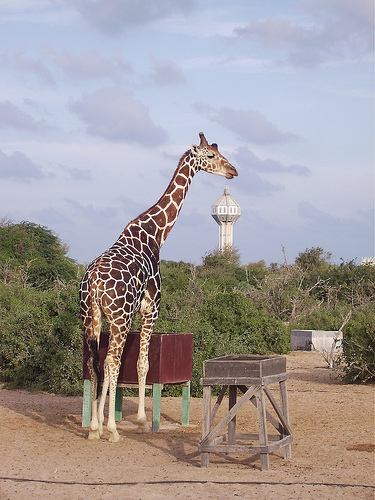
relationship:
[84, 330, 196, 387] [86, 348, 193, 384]
box has water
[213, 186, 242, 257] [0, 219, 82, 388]
tower over tree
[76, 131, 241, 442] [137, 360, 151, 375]
giraffe has knee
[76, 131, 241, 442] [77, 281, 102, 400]
giraffe has tail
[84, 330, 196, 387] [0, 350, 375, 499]
box in sand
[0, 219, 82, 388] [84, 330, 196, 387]
tree near box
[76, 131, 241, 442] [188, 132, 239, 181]
giraffe has head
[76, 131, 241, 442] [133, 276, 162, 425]
giraffe has leg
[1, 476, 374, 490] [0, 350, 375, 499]
shadow on sand